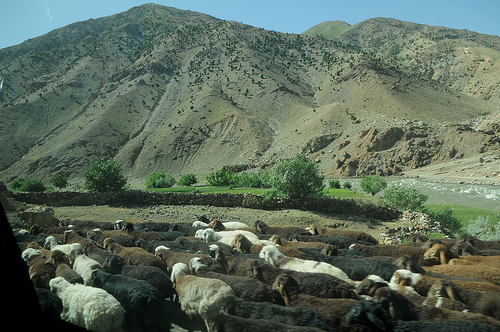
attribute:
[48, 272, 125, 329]
sheep — white, fluffy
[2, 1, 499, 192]
mountain — large, distant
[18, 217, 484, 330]
sheep — brown, grey, black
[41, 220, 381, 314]
sheep — grazing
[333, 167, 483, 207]
river — small